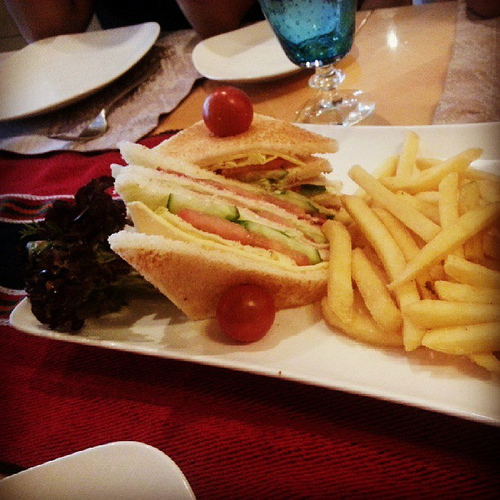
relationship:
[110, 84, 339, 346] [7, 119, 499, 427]
sandwich on top of plate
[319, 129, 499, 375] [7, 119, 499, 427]
french fries on top of plate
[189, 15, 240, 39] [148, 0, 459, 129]
elbow on top of table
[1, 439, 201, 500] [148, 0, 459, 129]
plate on top of table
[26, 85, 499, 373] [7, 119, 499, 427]
food on top of plate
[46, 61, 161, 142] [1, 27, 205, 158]
fork on top of placemat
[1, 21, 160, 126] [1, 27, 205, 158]
plate on top of placemat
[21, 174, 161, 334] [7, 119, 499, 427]
garnish on corner of plate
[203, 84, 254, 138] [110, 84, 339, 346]
cherry tomato on top of sandwich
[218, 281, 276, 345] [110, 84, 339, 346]
cherry tomato on top of sandwich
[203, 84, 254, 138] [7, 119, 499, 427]
cherry tomato on top of plate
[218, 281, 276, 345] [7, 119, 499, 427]
cherry tomato on top of plate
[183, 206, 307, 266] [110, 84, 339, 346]
tomato sliced on sandwich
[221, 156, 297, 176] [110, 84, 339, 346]
tomato sliced on sandwich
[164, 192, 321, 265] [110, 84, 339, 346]
cucumber slices inside of sandwich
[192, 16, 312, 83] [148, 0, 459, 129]
plate on top of table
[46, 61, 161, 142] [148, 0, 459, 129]
fork on top of table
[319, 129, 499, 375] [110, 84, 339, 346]
french fries next to sandwich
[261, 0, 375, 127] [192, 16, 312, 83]
glass behind plate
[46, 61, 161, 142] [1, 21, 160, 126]
fork next to plate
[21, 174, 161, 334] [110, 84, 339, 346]
garnish next to sandwich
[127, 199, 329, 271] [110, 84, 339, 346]
cheese inside of sandwich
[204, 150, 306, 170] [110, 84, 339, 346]
cheese inside of sandwich